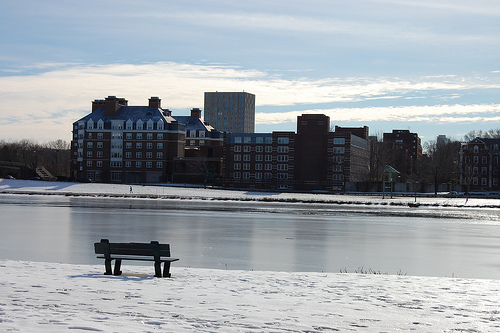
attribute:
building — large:
[68, 89, 223, 183]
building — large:
[228, 106, 424, 195]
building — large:
[62, 94, 226, 188]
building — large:
[223, 109, 422, 201]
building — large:
[435, 129, 495, 198]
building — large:
[69, 87, 228, 177]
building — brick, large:
[229, 110, 422, 190]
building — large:
[442, 134, 491, 200]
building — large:
[62, 90, 230, 192]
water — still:
[1, 199, 498, 284]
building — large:
[432, 133, 496, 197]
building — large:
[425, 130, 494, 200]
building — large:
[230, 110, 432, 198]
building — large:
[439, 134, 499, 191]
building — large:
[64, 100, 216, 185]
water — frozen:
[300, 220, 490, 260]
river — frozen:
[1, 195, 496, 275]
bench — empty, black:
[89, 235, 183, 278]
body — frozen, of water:
[5, 195, 493, 283]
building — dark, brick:
[70, 97, 228, 190]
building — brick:
[449, 130, 492, 194]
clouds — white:
[266, 73, 493, 105]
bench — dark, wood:
[90, 234, 180, 282]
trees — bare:
[21, 144, 56, 188]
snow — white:
[64, 243, 333, 330]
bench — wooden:
[98, 216, 194, 274]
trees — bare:
[402, 116, 479, 243]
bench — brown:
[94, 225, 194, 295]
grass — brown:
[331, 271, 411, 275]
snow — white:
[199, 267, 356, 315]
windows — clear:
[222, 141, 340, 171]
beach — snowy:
[69, 243, 281, 325]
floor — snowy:
[232, 294, 362, 314]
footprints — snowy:
[72, 274, 245, 300]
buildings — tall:
[72, 65, 362, 194]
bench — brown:
[42, 195, 213, 285]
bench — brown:
[89, 233, 195, 286]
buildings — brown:
[72, 71, 265, 173]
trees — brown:
[0, 142, 64, 167]